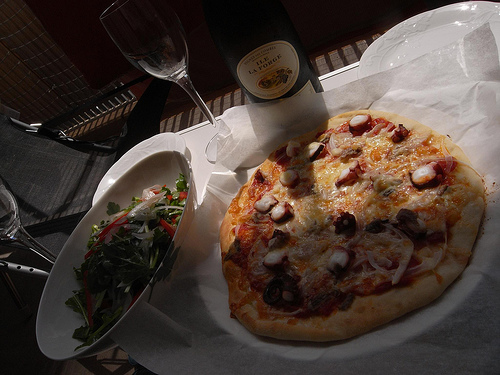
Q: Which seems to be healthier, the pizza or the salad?
A: The salad is healthier than the pizza.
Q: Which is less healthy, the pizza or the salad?
A: The pizza is less healthy than the salad.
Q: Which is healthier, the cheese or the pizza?
A: The cheese is healthier than the pizza.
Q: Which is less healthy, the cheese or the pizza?
A: The pizza is less healthy than the cheese.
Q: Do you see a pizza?
A: Yes, there is a pizza.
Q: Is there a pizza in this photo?
A: Yes, there is a pizza.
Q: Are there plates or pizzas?
A: Yes, there is a pizza.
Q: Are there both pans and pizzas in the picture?
A: No, there is a pizza but no pans.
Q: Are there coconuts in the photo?
A: No, there are no coconuts.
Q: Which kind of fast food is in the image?
A: The fast food is a pizza.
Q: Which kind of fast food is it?
A: The food is a pizza.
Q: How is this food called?
A: This is a pizza.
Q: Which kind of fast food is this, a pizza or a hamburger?
A: This is a pizza.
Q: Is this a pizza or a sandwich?
A: This is a pizza.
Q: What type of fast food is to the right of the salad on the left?
A: The food is a pizza.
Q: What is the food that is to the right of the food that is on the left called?
A: The food is a pizza.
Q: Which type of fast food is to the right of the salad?
A: The food is a pizza.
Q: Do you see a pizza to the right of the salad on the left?
A: Yes, there is a pizza to the right of the salad.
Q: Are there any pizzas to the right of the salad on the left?
A: Yes, there is a pizza to the right of the salad.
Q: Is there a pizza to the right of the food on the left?
A: Yes, there is a pizza to the right of the salad.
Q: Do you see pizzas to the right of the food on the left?
A: Yes, there is a pizza to the right of the salad.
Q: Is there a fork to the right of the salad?
A: No, there is a pizza to the right of the salad.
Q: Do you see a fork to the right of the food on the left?
A: No, there is a pizza to the right of the salad.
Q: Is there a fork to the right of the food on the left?
A: No, there is a pizza to the right of the salad.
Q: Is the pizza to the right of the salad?
A: Yes, the pizza is to the right of the salad.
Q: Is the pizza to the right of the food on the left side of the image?
A: Yes, the pizza is to the right of the salad.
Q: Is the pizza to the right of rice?
A: No, the pizza is to the right of the salad.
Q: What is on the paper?
A: The pizza is on the paper.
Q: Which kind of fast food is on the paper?
A: The food is a pizza.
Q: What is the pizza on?
A: The pizza is on the paper.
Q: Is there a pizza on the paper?
A: Yes, there is a pizza on the paper.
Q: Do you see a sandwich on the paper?
A: No, there is a pizza on the paper.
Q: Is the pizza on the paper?
A: Yes, the pizza is on the paper.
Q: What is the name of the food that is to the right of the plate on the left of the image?
A: The food is a pizza.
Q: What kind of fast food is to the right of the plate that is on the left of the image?
A: The food is a pizza.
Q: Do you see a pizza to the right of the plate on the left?
A: Yes, there is a pizza to the right of the plate.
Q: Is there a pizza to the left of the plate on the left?
A: No, the pizza is to the right of the plate.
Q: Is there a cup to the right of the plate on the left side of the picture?
A: No, there is a pizza to the right of the plate.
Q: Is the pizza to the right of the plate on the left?
A: Yes, the pizza is to the right of the plate.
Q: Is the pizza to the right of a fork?
A: No, the pizza is to the right of the plate.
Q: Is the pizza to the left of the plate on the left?
A: No, the pizza is to the right of the plate.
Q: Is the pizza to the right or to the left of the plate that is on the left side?
A: The pizza is to the right of the plate.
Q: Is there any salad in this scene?
A: Yes, there is salad.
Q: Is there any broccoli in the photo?
A: No, there is no broccoli.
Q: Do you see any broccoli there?
A: No, there is no broccoli.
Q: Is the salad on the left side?
A: Yes, the salad is on the left of the image.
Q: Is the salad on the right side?
A: No, the salad is on the left of the image.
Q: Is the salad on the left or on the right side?
A: The salad is on the left of the image.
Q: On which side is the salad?
A: The salad is on the left of the image.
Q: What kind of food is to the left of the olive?
A: The food is salad.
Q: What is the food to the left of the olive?
A: The food is salad.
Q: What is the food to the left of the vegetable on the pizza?
A: The food is salad.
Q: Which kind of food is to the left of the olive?
A: The food is salad.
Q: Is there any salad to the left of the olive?
A: Yes, there is salad to the left of the olive.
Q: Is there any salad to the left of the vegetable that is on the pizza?
A: Yes, there is salad to the left of the olive.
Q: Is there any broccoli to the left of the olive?
A: No, there is salad to the left of the olive.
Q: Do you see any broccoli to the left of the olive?
A: No, there is salad to the left of the olive.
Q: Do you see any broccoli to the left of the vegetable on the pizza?
A: No, there is salad to the left of the olive.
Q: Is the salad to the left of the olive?
A: Yes, the salad is to the left of the olive.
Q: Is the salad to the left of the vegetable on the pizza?
A: Yes, the salad is to the left of the olive.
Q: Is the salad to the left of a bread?
A: No, the salad is to the left of the olive.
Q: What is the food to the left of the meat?
A: The food is salad.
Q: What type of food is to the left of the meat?
A: The food is salad.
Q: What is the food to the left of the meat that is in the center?
A: The food is salad.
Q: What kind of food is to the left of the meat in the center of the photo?
A: The food is salad.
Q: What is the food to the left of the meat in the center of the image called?
A: The food is salad.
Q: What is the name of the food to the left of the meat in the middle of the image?
A: The food is salad.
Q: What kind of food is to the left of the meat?
A: The food is salad.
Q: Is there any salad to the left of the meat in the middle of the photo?
A: Yes, there is salad to the left of the meat.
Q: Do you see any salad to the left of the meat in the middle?
A: Yes, there is salad to the left of the meat.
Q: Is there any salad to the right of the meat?
A: No, the salad is to the left of the meat.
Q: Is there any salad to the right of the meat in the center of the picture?
A: No, the salad is to the left of the meat.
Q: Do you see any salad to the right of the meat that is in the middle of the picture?
A: No, the salad is to the left of the meat.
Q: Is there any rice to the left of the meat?
A: No, there is salad to the left of the meat.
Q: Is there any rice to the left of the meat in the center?
A: No, there is salad to the left of the meat.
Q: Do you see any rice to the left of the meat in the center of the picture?
A: No, there is salad to the left of the meat.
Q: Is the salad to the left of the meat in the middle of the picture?
A: Yes, the salad is to the left of the meat.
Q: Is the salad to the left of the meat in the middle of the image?
A: Yes, the salad is to the left of the meat.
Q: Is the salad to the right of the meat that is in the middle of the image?
A: No, the salad is to the left of the meat.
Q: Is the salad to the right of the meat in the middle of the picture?
A: No, the salad is to the left of the meat.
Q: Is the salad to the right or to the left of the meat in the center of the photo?
A: The salad is to the left of the meat.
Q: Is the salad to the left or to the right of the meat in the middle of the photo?
A: The salad is to the left of the meat.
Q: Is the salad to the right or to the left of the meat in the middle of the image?
A: The salad is to the left of the meat.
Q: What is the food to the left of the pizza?
A: The food is salad.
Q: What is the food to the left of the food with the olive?
A: The food is salad.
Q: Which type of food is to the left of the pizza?
A: The food is salad.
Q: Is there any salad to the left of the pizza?
A: Yes, there is salad to the left of the pizza.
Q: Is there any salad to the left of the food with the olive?
A: Yes, there is salad to the left of the pizza.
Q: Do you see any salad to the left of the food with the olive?
A: Yes, there is salad to the left of the pizza.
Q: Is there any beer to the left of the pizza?
A: No, there is salad to the left of the pizza.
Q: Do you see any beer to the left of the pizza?
A: No, there is salad to the left of the pizza.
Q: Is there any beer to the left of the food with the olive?
A: No, there is salad to the left of the pizza.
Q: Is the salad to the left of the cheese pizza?
A: Yes, the salad is to the left of the pizza.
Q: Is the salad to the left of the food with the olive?
A: Yes, the salad is to the left of the pizza.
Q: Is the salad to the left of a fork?
A: No, the salad is to the left of the pizza.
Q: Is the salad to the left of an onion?
A: Yes, the salad is to the left of an onion.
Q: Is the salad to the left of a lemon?
A: No, the salad is to the left of an onion.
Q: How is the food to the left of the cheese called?
A: The food is salad.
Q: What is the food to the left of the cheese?
A: The food is salad.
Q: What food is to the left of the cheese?
A: The food is salad.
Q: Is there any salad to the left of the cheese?
A: Yes, there is salad to the left of the cheese.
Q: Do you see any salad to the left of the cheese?
A: Yes, there is salad to the left of the cheese.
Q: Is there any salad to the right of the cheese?
A: No, the salad is to the left of the cheese.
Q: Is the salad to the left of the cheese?
A: Yes, the salad is to the left of the cheese.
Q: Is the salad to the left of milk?
A: No, the salad is to the left of the cheese.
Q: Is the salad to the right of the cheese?
A: No, the salad is to the left of the cheese.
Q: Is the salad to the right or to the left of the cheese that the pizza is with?
A: The salad is to the left of the cheese.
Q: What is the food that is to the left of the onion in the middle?
A: The food is salad.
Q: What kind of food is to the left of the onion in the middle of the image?
A: The food is salad.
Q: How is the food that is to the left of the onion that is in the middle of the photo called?
A: The food is salad.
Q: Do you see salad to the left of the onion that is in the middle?
A: Yes, there is salad to the left of the onion.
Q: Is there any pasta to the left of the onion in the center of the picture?
A: No, there is salad to the left of the onion.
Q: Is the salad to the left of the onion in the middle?
A: Yes, the salad is to the left of the onion.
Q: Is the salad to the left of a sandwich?
A: No, the salad is to the left of the onion.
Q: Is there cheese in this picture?
A: Yes, there is cheese.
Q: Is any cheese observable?
A: Yes, there is cheese.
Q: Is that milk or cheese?
A: That is cheese.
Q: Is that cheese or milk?
A: That is cheese.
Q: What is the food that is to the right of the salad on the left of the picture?
A: The food is cheese.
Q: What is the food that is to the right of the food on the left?
A: The food is cheese.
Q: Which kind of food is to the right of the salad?
A: The food is cheese.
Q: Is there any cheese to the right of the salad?
A: Yes, there is cheese to the right of the salad.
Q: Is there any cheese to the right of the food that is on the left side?
A: Yes, there is cheese to the right of the salad.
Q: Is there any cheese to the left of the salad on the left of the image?
A: No, the cheese is to the right of the salad.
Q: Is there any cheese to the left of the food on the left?
A: No, the cheese is to the right of the salad.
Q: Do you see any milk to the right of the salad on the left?
A: No, there is cheese to the right of the salad.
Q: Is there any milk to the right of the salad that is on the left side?
A: No, there is cheese to the right of the salad.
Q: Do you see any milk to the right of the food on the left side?
A: No, there is cheese to the right of the salad.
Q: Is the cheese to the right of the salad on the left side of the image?
A: Yes, the cheese is to the right of the salad.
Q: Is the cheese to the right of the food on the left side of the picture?
A: Yes, the cheese is to the right of the salad.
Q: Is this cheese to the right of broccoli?
A: No, the cheese is to the right of the salad.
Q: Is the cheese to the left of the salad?
A: No, the cheese is to the right of the salad.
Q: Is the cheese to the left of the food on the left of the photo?
A: No, the cheese is to the right of the salad.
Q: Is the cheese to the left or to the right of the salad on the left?
A: The cheese is to the right of the salad.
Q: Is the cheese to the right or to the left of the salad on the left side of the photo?
A: The cheese is to the right of the salad.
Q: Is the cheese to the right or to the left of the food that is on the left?
A: The cheese is to the right of the salad.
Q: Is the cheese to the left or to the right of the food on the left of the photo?
A: The cheese is to the right of the salad.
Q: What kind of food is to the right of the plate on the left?
A: The food is cheese.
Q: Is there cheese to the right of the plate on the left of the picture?
A: Yes, there is cheese to the right of the plate.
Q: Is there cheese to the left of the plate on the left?
A: No, the cheese is to the right of the plate.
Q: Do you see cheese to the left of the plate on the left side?
A: No, the cheese is to the right of the plate.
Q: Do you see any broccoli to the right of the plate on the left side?
A: No, there is cheese to the right of the plate.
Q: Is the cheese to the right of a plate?
A: Yes, the cheese is to the right of a plate.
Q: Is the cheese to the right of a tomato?
A: No, the cheese is to the right of a plate.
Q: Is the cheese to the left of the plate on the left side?
A: No, the cheese is to the right of the plate.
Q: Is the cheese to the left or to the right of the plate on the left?
A: The cheese is to the right of the plate.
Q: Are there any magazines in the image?
A: No, there are no magazines.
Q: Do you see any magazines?
A: No, there are no magazines.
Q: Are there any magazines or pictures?
A: No, there are no magazines or pictures.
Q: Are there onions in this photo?
A: Yes, there is an onion.